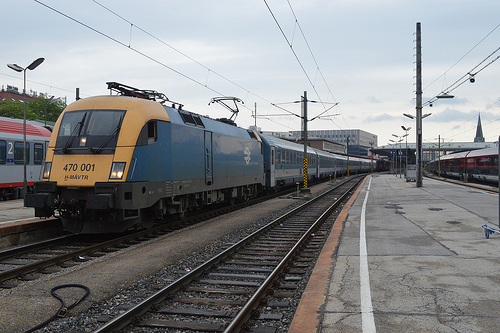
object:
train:
[25, 96, 390, 235]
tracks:
[0, 175, 370, 331]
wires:
[32, 1, 500, 140]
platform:
[305, 170, 499, 326]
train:
[1, 118, 47, 203]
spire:
[469, 109, 488, 143]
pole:
[407, 20, 436, 189]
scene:
[5, 4, 499, 331]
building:
[267, 128, 376, 146]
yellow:
[41, 95, 171, 187]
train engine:
[25, 87, 267, 235]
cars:
[265, 134, 391, 196]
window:
[146, 120, 160, 146]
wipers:
[61, 111, 87, 154]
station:
[6, 160, 500, 332]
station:
[363, 138, 500, 171]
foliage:
[3, 96, 66, 118]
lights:
[43, 161, 54, 179]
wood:
[217, 256, 266, 280]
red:
[3, 123, 44, 136]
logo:
[244, 147, 252, 164]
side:
[155, 105, 261, 200]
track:
[0, 210, 153, 290]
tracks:
[88, 174, 367, 333]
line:
[358, 175, 376, 332]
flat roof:
[289, 129, 379, 135]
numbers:
[63, 163, 96, 172]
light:
[108, 161, 127, 180]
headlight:
[78, 136, 88, 147]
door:
[200, 124, 216, 188]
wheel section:
[140, 169, 366, 228]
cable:
[20, 284, 91, 333]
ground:
[102, 260, 135, 333]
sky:
[36, 2, 484, 87]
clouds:
[48, 36, 252, 72]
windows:
[51, 111, 128, 155]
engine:
[39, 90, 269, 230]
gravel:
[185, 248, 212, 261]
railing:
[0, 172, 357, 290]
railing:
[94, 173, 366, 333]